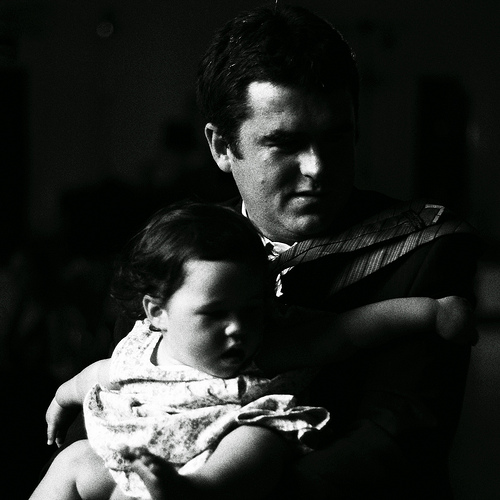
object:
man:
[113, 1, 482, 499]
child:
[40, 198, 484, 499]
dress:
[80, 317, 334, 495]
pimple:
[256, 177, 270, 189]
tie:
[270, 199, 471, 311]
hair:
[191, 3, 360, 163]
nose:
[298, 141, 326, 183]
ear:
[202, 119, 232, 174]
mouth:
[290, 182, 328, 203]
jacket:
[119, 184, 479, 499]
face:
[181, 263, 270, 378]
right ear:
[140, 292, 166, 333]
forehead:
[186, 256, 270, 301]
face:
[246, 110, 349, 233]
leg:
[181, 426, 295, 498]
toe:
[115, 442, 131, 460]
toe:
[135, 447, 143, 467]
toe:
[141, 453, 158, 465]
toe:
[148, 463, 166, 478]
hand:
[435, 294, 481, 351]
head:
[113, 201, 274, 379]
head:
[201, 6, 358, 237]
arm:
[52, 356, 143, 408]